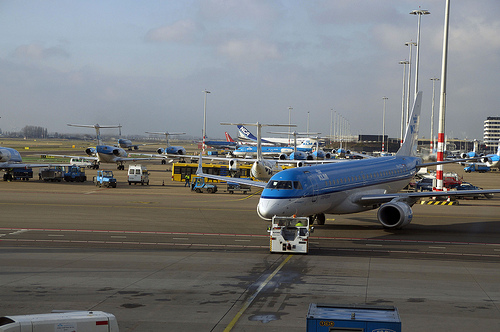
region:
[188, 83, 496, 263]
blue and white airplane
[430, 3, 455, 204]
light pole on airport grounds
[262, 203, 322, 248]
airplane service vehicle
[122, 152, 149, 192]
van driving on airport grounds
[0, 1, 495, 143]
weather is partly cloudy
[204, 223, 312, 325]
yellow painted track on airport ground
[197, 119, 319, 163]
airplanes parked at terminal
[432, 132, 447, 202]
red and white stripes painted on pole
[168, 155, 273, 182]
yellow bus parked next to airplane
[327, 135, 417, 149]
airport terminal building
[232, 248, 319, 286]
oil slick on tarmac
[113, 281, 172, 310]
black round spot on ground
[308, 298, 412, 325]
white edge of container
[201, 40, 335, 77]
dark blue and white skies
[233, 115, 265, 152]
blue and white tail of airplane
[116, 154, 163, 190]
white van on ground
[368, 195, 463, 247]
large silver wings on side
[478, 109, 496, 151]
large black and white building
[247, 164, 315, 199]
window on front of plane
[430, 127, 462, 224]
red and white color on pole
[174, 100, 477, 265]
Air liner painted blue and white.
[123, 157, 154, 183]
White van on runway.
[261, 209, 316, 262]
White pushback tractor.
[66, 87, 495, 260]
Several airplanes on a runway.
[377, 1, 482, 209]
White light poles.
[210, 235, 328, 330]
Small puddles of water.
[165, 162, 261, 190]
Large yellow bus.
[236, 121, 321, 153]
White air liner with blue paint on tail.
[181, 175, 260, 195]
Blue luggage dolly.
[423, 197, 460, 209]
Yellow and black hazard paint on base of light pole.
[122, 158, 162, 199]
white car next to the planes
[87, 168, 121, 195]
blue motor vehicle next to the white car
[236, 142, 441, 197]
blue top trim on the plane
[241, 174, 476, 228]
white bottom trim on the plane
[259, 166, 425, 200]
black middle trim on the plane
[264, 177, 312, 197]
front window of the plane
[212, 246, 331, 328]
wetness on the ground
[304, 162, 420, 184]
windows on the side of the plane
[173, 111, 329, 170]
planes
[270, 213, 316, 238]
people in the motor vehicle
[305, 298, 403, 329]
A blue container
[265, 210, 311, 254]
A maintenance vehicle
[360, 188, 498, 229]
An engine attached to the wing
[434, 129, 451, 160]
Red and white stripes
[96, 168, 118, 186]
A blue jeep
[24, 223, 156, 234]
Red and white paint on the ground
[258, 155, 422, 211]
A blue and white airplane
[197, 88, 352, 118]
Airport and tarmac lights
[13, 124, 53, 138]
Trees in the background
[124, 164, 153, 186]
A white van